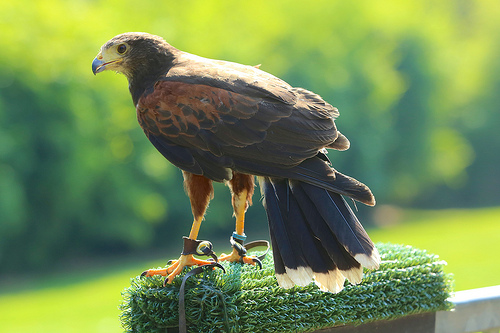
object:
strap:
[228, 230, 271, 261]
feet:
[138, 254, 227, 286]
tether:
[174, 235, 222, 333]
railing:
[433, 285, 500, 332]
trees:
[0, 2, 499, 279]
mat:
[117, 240, 460, 333]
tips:
[350, 247, 383, 272]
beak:
[90, 54, 120, 76]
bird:
[90, 32, 385, 297]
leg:
[225, 170, 255, 252]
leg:
[181, 170, 215, 258]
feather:
[298, 181, 381, 271]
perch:
[119, 238, 459, 332]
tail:
[262, 148, 379, 296]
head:
[91, 30, 171, 81]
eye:
[114, 42, 130, 54]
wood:
[393, 318, 425, 332]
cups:
[178, 235, 272, 257]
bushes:
[0, 0, 499, 276]